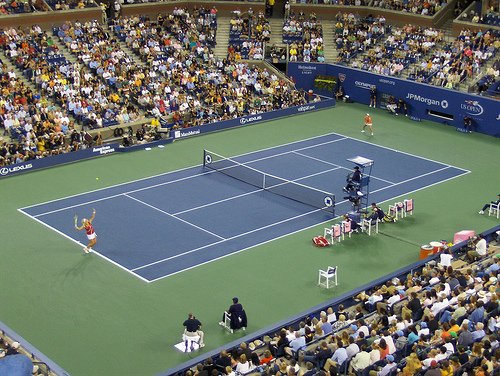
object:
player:
[73, 212, 102, 257]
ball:
[93, 177, 99, 183]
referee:
[347, 158, 372, 209]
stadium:
[1, 1, 500, 373]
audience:
[0, 2, 499, 176]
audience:
[159, 223, 497, 375]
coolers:
[421, 229, 478, 264]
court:
[18, 130, 472, 286]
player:
[363, 113, 375, 140]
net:
[200, 149, 341, 215]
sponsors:
[452, 96, 489, 121]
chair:
[319, 265, 340, 290]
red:
[83, 223, 96, 236]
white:
[87, 236, 97, 242]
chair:
[350, 156, 373, 208]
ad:
[404, 89, 452, 114]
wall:
[291, 60, 499, 141]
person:
[403, 351, 421, 372]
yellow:
[405, 352, 418, 375]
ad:
[3, 161, 32, 178]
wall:
[0, 85, 335, 186]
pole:
[202, 151, 210, 170]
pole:
[331, 185, 336, 220]